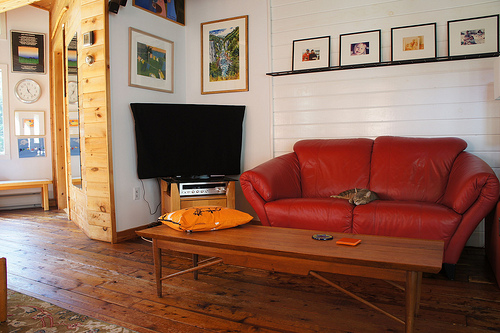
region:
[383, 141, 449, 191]
right side of red couch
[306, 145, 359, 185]
left side of red couch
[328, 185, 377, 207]
cat in middle of couch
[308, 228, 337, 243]
ashtray on top of table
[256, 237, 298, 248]
top of wooden table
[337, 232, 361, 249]
orange wallet on table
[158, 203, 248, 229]
yellow pillow on table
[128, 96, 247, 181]
big black flatscreen tv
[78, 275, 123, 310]
brown hardwood plat floor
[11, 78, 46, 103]
silver lined clock on wall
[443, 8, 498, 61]
The picture is rectangular.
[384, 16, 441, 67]
The picture is rectangular.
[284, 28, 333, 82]
The picture is rectangular.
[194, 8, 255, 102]
The picture is rectangular.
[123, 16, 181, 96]
The picture is rectangular.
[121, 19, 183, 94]
The picture is framed.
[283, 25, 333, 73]
The picture is framed.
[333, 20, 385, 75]
The picture is framed.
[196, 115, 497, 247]
a couch in a house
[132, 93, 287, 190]
a tv in a house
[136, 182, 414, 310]
a table in a house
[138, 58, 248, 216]
a flat screen tv in a house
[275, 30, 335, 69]
pictures in a house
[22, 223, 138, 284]
a wood floor in a house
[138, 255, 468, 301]
the legs on a table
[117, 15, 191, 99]
a picture on a wall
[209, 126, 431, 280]
a red couch near a table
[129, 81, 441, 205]
a tv near a couch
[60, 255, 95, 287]
Part of the wood floor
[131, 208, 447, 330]
A wood table on the floor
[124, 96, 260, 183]
A TV on the table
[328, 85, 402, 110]
Part of the white wall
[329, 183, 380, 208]
A cat sitting on the couch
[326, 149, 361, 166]
Part of the red couch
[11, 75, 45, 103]
A clock on the wall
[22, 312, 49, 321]
Part of the carpet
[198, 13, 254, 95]
A picture hanging on the wall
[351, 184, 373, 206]
The head of the cat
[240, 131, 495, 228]
Cat lying on red couch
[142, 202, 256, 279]
Orange pillow on table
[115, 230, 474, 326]
Brown coffee table on wood flooring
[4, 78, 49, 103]
A clock hanging on wall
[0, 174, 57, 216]
Bench on wooden flooring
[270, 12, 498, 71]
Four pictures sitting on a shelf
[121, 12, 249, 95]
Two pictures hanging on wall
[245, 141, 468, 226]
Brown cat sleeping on red couch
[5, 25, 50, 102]
Picture hanging on wall above a clock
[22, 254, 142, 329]
Carpet on wood flooring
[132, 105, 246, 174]
A black flat screen television.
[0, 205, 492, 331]
Dark brown hardwood floors.